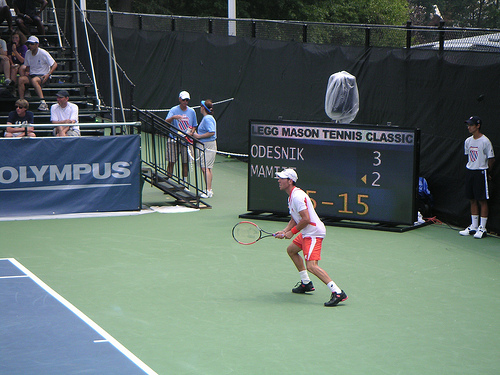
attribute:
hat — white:
[274, 167, 299, 182]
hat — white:
[178, 90, 191, 100]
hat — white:
[26, 35, 41, 43]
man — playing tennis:
[272, 166, 347, 308]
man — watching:
[16, 35, 59, 109]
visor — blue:
[200, 99, 213, 114]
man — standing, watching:
[458, 114, 497, 240]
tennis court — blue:
[1, 259, 155, 375]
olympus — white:
[0, 162, 131, 185]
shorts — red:
[293, 233, 325, 261]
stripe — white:
[306, 237, 317, 259]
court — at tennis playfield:
[1, 109, 500, 373]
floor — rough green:
[0, 105, 497, 373]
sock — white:
[299, 270, 310, 284]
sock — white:
[327, 281, 340, 295]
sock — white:
[470, 212, 479, 228]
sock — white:
[479, 216, 489, 229]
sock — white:
[182, 174, 190, 185]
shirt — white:
[286, 187, 325, 237]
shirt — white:
[462, 135, 496, 172]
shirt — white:
[48, 103, 80, 130]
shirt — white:
[21, 47, 55, 79]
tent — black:
[404, 30, 499, 50]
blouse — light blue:
[198, 116, 218, 143]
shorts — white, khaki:
[197, 140, 218, 170]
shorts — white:
[164, 136, 191, 166]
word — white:
[249, 144, 305, 162]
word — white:
[249, 164, 297, 179]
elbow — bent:
[300, 215, 312, 224]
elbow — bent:
[209, 130, 215, 136]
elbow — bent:
[52, 60, 60, 69]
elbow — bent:
[5, 125, 14, 133]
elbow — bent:
[28, 126, 34, 130]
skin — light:
[286, 213, 311, 238]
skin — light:
[305, 260, 337, 285]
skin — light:
[285, 242, 306, 272]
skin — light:
[15, 75, 46, 101]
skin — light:
[468, 198, 488, 218]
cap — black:
[464, 116, 483, 127]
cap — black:
[54, 89, 69, 98]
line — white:
[8, 257, 159, 375]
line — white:
[92, 338, 106, 344]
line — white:
[1, 274, 28, 278]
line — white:
[1, 257, 12, 261]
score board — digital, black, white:
[246, 118, 419, 227]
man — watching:
[49, 89, 82, 137]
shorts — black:
[464, 166, 491, 201]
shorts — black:
[25, 72, 50, 82]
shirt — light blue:
[166, 105, 198, 140]